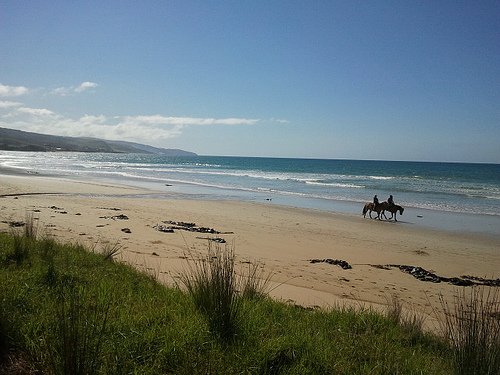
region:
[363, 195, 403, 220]
two people riding horses on the beach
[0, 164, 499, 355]
a yellow, sandy beach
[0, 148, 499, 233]
a calm, blue ocean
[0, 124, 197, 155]
a hill behind the beach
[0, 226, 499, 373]
a grassy area in front of the beach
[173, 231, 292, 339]
a tall clump of grass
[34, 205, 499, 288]
flat rocks on the beach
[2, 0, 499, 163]
a clear blue sky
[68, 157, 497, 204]
gentle waves in the ocean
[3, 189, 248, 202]
a small stream leading to the ocean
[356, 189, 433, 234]
two horses on a beac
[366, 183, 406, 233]
two people riding horses on a beach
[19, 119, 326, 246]
a beach by the ocean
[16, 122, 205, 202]
mountains by a ocean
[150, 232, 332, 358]
tall patch of grass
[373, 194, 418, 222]
a horse with its head down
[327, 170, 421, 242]
two horses walking on a beach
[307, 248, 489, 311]
seaweed on a beach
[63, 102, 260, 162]
white clouds in the sky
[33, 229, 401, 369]
grass next to a beach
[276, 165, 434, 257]
two people riding horses on beach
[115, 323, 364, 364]
short green grass in foreground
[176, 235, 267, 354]
clumps of tall grass in foreground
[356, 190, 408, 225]
two people on two horses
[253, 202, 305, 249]
sand on the beach is light brown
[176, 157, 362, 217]
waves are small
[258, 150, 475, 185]
blue water is calm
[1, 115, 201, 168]
low mountains in the far distance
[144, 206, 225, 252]
debris washed up on shore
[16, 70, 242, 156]
horizontal clouds in sky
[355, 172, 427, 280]
the horse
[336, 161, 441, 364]
the horse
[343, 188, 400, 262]
the horse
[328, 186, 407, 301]
the horse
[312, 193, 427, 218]
the horse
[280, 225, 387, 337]
sea weed on the beach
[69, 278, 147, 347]
short and tall green grass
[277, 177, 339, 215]
sand and blue water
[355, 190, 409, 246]
two people riding horses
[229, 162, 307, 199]
blue water with white waves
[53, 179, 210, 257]
a small inlet of water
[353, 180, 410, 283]
two people riding horses by the beach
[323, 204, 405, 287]
two horses on sand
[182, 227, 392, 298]
foot prints in the sand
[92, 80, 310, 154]
white clouds in the sky